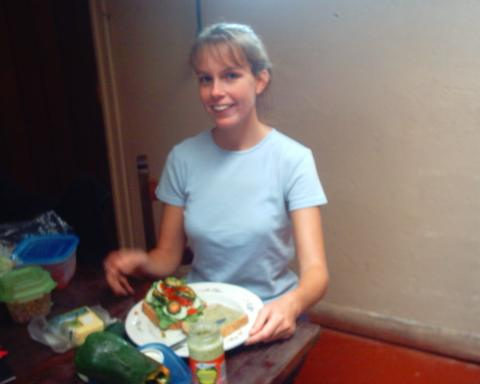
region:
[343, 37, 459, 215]
white walls of the room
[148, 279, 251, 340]
a sandwich on a white plate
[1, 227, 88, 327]
containers with food inside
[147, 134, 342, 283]
the woman's light blue t-shirt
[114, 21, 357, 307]
a woman wearing a blue shirt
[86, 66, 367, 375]
a woman sitting at a table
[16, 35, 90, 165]
wood paneled walls of the next room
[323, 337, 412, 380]
brown floors of the room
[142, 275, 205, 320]
veggies on a slice of bread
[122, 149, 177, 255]
wood back of the chair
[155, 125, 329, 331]
woman wearing a baby blue shirt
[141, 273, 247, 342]
a sandwich on a plate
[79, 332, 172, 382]
a green pepper on a table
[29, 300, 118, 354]
a square of cheese in a sealed bag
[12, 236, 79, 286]
a plastic container with a blue lid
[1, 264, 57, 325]
a plastic container containing beans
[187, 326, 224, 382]
an opened jar on a table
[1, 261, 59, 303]
green lid of a container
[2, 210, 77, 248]
a plastic wrapper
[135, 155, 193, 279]
wooden seat of a chair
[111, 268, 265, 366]
plate full of food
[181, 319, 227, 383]
jar with lid taken off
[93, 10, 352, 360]
person holding a plate of food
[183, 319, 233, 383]
jar with red label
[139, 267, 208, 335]
bread with toppings on a plate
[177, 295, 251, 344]
slice of bread on a plate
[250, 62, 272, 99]
ear of a person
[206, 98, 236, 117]
mouth of a person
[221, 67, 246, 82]
eye of a person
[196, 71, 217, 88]
eye of a person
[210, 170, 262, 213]
the shirt is pale blue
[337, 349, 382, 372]
the floor is brown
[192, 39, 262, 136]
the lady is smiling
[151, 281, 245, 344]
the sandwhich is on the plate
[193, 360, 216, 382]
the lable is red and yellow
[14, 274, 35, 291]
the lid is light green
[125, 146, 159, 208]
the chair is dark brown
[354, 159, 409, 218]
the walll is white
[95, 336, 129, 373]
the veggie is green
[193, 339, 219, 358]
the jar has a white substance in it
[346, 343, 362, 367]
part of a floor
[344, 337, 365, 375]
part of a floor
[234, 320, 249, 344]
part of a plate